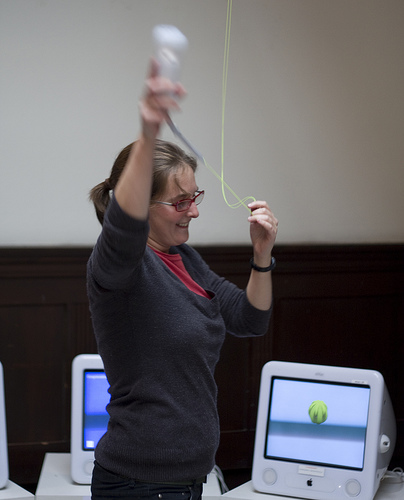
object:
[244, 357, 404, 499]
computer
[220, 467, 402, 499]
desk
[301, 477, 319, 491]
logo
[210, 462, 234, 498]
cord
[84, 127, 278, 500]
woman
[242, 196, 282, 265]
hand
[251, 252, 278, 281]
watch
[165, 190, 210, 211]
glasses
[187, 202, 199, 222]
nose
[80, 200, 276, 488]
shirt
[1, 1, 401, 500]
wall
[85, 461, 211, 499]
jeans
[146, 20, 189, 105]
remote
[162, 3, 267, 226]
string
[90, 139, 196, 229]
hair